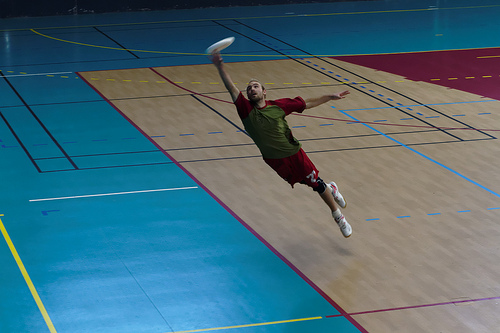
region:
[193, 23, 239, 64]
white plastic frisbee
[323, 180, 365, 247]
pair of white tennis shoes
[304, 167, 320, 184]
design on leg of shorts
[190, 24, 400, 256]
man jumping to catch frisbee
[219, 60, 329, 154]
man in green and red shirt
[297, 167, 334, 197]
black knee guard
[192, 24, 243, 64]
white frisbee in air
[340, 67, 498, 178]
lines painted on floor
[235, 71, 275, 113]
man with brown hair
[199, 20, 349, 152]
man catching white frisbee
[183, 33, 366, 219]
One man is trying to catch the Frisbee.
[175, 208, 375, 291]
Ground is blue, brown and red color.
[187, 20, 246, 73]
Frisbee is white color.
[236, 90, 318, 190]
Man is wearing red and green dress.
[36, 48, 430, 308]
Lines are drawn in ground.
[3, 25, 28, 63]
Light reflection is seen in ground.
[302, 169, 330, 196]
Knee cap is black color.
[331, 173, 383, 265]
Man is wearing white shoes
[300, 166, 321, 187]
Letters are white color.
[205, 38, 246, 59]
Frisbee is in air.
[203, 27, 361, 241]
a man trying to catch a frisbee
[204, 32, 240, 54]
a white frisbee in flight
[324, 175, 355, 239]
a pair of red and white sneakers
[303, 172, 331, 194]
a black athletic knee brace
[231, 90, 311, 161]
a red and green t-shirt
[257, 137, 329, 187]
a pair of red athletic shorts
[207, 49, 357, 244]
a male athlete in mid-air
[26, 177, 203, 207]
a white dividing line on a blue floor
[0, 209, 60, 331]
a yellow dividing line on a blue floor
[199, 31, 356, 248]
an athlete narrowly missing a frisbee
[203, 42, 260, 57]
a frisbee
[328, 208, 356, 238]
white shoes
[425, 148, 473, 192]
blue line on the court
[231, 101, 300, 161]
a green and red shirt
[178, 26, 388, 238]
a person jumping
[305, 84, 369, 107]
hands are out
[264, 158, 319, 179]
man is wearing red shorts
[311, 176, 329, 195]
a black knee brace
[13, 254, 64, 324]
a yellow line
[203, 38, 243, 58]
a flying frisbee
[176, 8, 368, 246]
a man catching a white frisbee.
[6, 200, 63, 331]
a yellow line on the ground.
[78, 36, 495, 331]
a paved ground.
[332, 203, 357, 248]
a left foot shoe.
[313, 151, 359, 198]
a right foot shoe.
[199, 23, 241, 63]
a white frisbee.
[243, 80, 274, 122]
a man with hair.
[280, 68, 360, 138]
a left human arm.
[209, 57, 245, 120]
a right human arm.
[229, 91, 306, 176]
a man wearing a shirt.